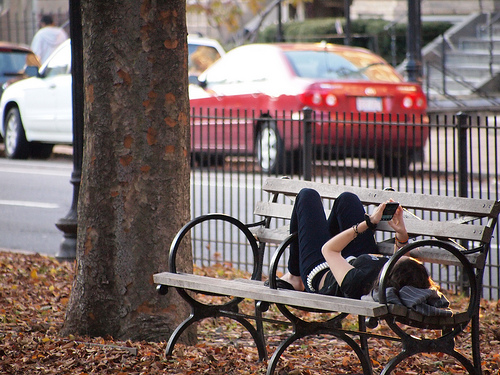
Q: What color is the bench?
A: Brown and black.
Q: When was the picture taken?
A: Daytime.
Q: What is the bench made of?
A: Wood and metal.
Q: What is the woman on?
A: The bench.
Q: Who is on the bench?
A: The woman.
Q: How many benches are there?
A: One.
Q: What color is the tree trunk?
A: Brown.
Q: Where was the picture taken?
A: In a city park.